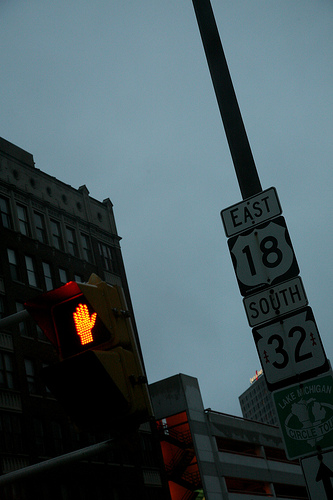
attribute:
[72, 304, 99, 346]
hand — glowing, illuminated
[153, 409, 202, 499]
light — glowing, red, black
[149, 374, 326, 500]
garage — multi-floored, rain-soaked, parking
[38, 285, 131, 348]
sign — orange, don't cross, electric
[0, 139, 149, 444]
building — tall, dark, multistory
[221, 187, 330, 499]
sign — tall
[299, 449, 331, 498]
sign — black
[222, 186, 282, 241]
sign — black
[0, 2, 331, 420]
sky — overcast